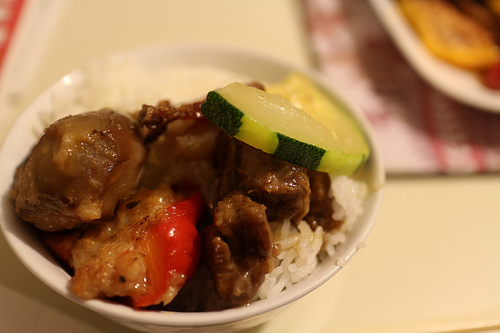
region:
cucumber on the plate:
[217, 79, 414, 179]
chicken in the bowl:
[5, 71, 152, 227]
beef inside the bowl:
[203, 172, 318, 317]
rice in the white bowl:
[276, 221, 331, 280]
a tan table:
[398, 199, 484, 309]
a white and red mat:
[395, 75, 455, 161]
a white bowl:
[260, 248, 351, 308]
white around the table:
[6, 15, 53, 69]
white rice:
[99, 75, 155, 104]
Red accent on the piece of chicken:
[146, 193, 192, 328]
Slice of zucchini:
[212, 76, 343, 167]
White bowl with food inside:
[30, 49, 382, 326]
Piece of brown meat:
[7, 105, 162, 243]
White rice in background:
[40, 50, 230, 97]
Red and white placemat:
[311, 12, 498, 177]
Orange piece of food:
[405, 2, 492, 62]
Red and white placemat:
[5, 0, 57, 100]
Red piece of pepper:
[135, 204, 200, 309]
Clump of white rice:
[261, 187, 381, 322]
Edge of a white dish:
[367, 0, 494, 113]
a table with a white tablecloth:
[400, 240, 463, 322]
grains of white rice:
[281, 257, 313, 277]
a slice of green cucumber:
[243, 98, 309, 145]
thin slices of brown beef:
[223, 198, 288, 257]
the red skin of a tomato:
[164, 209, 204, 276]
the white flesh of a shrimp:
[89, 228, 132, 271]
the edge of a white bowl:
[154, 45, 210, 63]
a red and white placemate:
[334, 25, 376, 76]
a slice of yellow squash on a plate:
[429, 16, 486, 63]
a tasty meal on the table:
[0, 40, 472, 330]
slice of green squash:
[203, 80, 368, 171]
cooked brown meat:
[27, 126, 234, 281]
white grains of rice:
[271, 225, 319, 273]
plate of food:
[6, 50, 372, 330]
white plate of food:
[2, 56, 388, 328]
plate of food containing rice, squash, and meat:
[4, 45, 387, 331]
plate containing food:
[376, 1, 498, 121]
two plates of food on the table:
[1, 1, 495, 331]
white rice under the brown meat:
[216, 166, 320, 278]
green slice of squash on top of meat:
[163, 82, 350, 178]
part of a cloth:
[430, 130, 460, 148]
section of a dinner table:
[404, 239, 425, 264]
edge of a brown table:
[448, 323, 485, 327]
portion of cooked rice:
[297, 249, 312, 259]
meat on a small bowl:
[79, 132, 101, 162]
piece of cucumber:
[262, 113, 288, 128]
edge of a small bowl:
[353, 230, 360, 250]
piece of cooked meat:
[236, 242, 266, 264]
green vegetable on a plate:
[268, 115, 300, 126]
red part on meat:
[167, 237, 189, 257]